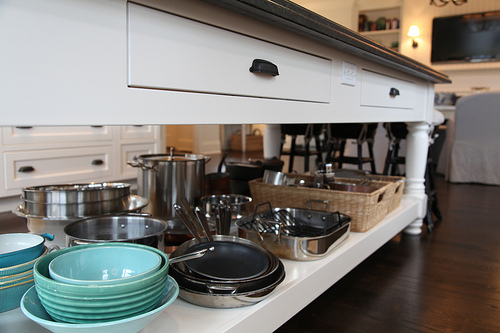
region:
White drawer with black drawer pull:
[124, 0, 333, 105]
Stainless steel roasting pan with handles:
[232, 198, 349, 259]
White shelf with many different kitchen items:
[0, 145, 405, 330]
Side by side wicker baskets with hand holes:
[245, 166, 405, 231]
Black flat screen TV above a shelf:
[426, 10, 496, 60]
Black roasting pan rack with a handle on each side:
[243, 199, 342, 234]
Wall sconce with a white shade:
[403, 22, 423, 49]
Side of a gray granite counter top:
[264, 0, 483, 85]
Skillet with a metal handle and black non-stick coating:
[182, 207, 270, 281]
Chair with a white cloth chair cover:
[433, 86, 498, 185]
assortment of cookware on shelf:
[4, 138, 259, 330]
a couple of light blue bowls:
[28, 247, 163, 320]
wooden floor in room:
[395, 250, 492, 321]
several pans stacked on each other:
[167, 198, 286, 303]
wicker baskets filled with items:
[246, 159, 410, 214]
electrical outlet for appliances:
[331, 63, 361, 89]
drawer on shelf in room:
[116, 17, 342, 116]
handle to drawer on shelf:
[244, 58, 283, 77]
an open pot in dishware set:
[61, 212, 163, 247]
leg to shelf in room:
[398, 123, 429, 238]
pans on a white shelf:
[179, 229, 283, 321]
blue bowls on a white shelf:
[27, 248, 145, 330]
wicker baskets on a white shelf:
[259, 165, 416, 218]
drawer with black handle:
[123, 0, 355, 113]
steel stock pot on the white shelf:
[128, 146, 214, 211]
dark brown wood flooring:
[382, 257, 467, 322]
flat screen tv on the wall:
[426, 8, 498, 63]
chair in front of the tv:
[449, 77, 499, 194]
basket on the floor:
[239, 128, 261, 153]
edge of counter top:
[303, 13, 447, 73]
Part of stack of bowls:
[1, 227, 44, 318]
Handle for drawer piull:
[246, 58, 281, 78]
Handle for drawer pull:
[384, 82, 402, 99]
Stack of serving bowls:
[19, 237, 178, 329]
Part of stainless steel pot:
[123, 141, 211, 192]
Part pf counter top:
[336, 22, 389, 62]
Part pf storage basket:
[351, 196, 378, 208]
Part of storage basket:
[395, 180, 405, 195]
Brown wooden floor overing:
[391, 277, 452, 325]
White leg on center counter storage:
[410, 126, 426, 203]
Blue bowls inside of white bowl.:
[47, 248, 129, 329]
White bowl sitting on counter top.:
[89, 294, 149, 329]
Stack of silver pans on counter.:
[203, 225, 250, 312]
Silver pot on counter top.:
[73, 209, 173, 249]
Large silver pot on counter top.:
[136, 143, 210, 240]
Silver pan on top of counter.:
[251, 192, 368, 276]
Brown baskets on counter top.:
[268, 165, 410, 207]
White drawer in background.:
[18, 141, 120, 180]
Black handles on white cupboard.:
[10, 160, 123, 171]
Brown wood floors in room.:
[398, 249, 479, 329]